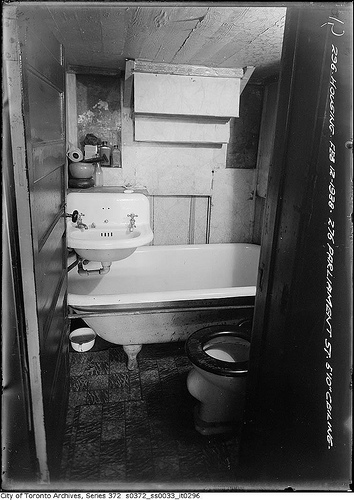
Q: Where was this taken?
A: Bathroom.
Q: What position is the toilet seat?
A: Down.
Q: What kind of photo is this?
A: Black and white.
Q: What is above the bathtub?
A: Sink.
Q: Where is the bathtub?
A: Below the sink.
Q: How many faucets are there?
A: 2.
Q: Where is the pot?
A: Under the tub.